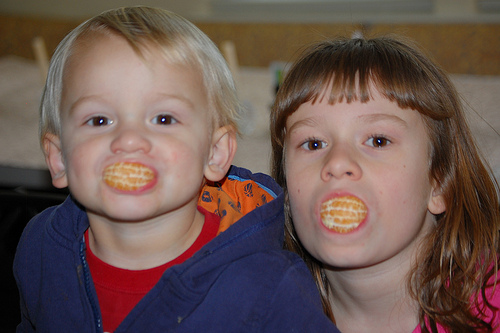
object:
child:
[270, 34, 500, 333]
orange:
[99, 162, 154, 190]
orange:
[321, 195, 368, 234]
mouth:
[102, 158, 164, 197]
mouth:
[308, 188, 372, 236]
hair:
[36, 4, 241, 143]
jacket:
[0, 167, 336, 332]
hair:
[268, 36, 500, 332]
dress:
[412, 252, 499, 333]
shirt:
[78, 208, 220, 333]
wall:
[0, 0, 497, 187]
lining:
[197, 176, 274, 236]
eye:
[147, 111, 184, 127]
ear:
[202, 125, 237, 183]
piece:
[103, 162, 156, 178]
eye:
[296, 136, 329, 153]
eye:
[361, 133, 398, 152]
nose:
[316, 130, 362, 183]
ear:
[429, 131, 455, 216]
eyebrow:
[354, 111, 411, 128]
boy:
[2, 6, 338, 332]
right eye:
[79, 110, 115, 130]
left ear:
[204, 125, 239, 182]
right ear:
[39, 130, 68, 189]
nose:
[110, 105, 153, 156]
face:
[58, 36, 213, 223]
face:
[282, 98, 427, 262]